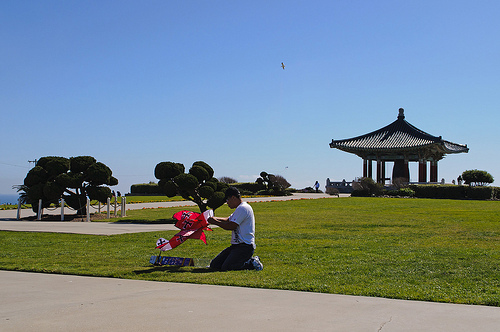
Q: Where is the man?
A: On the ground.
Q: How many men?
A: One.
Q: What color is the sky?
A: Blue.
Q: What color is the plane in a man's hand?
A: Red.